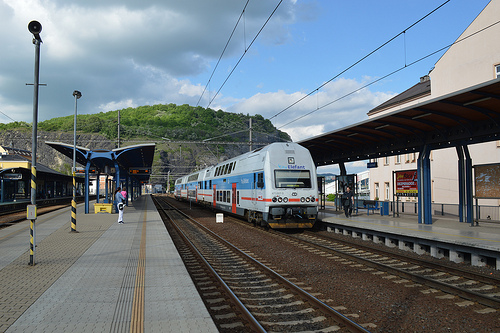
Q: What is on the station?
A: Train.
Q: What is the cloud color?
A: Grey.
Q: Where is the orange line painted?
A: On the platform.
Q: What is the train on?
A: Tracks.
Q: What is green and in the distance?
A: Trees.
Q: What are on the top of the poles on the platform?
A: Speakers.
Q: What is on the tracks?
A: The train.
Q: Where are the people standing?
A: The platform.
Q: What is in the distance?
A: A mountain.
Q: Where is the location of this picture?
A: A train station.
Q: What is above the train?
A: Wires.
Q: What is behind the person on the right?
A: Benches.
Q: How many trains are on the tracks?
A: One.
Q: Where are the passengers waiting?
A: On the platform.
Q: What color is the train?
A: Blue and grey.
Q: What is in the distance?
A: Hill with trees.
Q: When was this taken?
A: During the day.